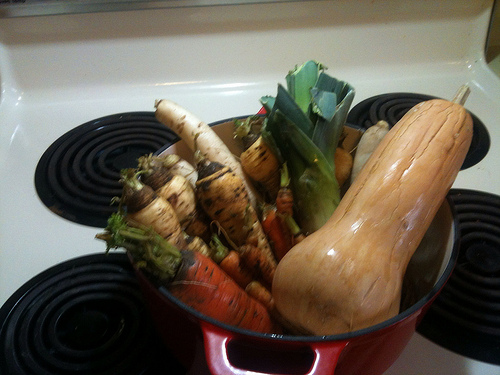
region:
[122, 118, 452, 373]
The red pot on the stove.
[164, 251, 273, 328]
The orange carrot in the pot.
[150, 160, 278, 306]
The tan carrots in the pot.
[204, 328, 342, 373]
The handle of the pot.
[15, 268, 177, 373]
The bottom left grill on the stove.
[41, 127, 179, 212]
The top left grill on the stove.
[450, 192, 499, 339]
The bottom right grill on the stove.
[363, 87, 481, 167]
The right top grill on the stove.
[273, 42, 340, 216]
The green leaves in the pot.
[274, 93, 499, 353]
The big tan vegetable in the pot.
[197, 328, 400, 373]
red pot with a handle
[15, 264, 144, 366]
black burner on an electric stove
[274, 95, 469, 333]
long squash in a pot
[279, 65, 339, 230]
green vegetable in a pot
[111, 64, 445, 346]
red pot full of vegetables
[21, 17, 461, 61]
white stove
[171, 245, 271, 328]
large orange carrot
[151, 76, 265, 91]
reflection of light on the stove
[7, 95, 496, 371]
four burners on a kitchen stove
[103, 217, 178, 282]
green top of a carrot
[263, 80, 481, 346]
this is a gourd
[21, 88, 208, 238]
this is a stove eye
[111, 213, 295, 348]
this is a carrot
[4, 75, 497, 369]
these are stove eyes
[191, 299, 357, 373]
this is a handle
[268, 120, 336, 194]
this is a leaf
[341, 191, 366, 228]
this is the color tan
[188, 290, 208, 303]
this is the color orange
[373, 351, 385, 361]
this is the color red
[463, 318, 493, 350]
this is the color black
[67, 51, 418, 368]
Vegetables in the bowl.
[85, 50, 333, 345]
Carrots in the pot.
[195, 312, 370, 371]
Handle on the pot.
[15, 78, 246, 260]
Burner on the stove.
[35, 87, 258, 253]
Black burner on the stove.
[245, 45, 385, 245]
Green leaves on the vegetables.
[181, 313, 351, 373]
Red handle on the pot.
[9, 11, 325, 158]
White stove .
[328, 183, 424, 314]
Shine on the veggies.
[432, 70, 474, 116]
Stem on the veggies.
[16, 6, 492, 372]
picture taken indoors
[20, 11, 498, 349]
picture taken inside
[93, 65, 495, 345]
vegetables in a bowl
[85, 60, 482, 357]
the bowl is on the oven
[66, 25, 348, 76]
the oven is white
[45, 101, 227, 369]
the oven has electric burners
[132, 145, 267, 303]
carrots in the bowl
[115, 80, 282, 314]
the carrots are dirty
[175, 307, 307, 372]
the bowl is shiny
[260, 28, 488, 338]
a squash in the bowl